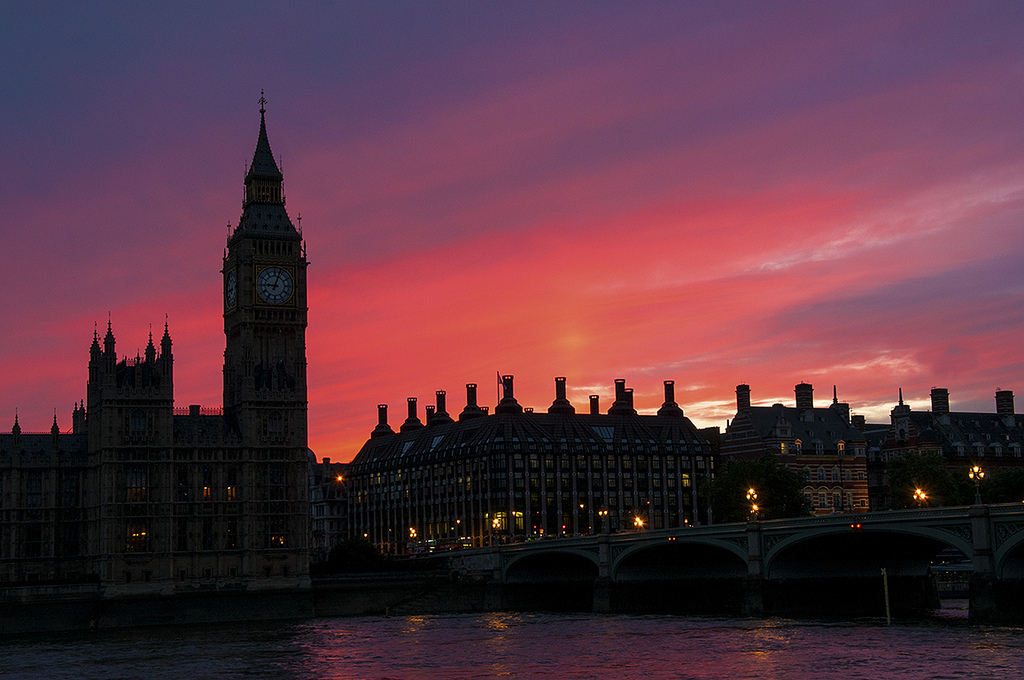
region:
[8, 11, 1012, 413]
The sky at dusk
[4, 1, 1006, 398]
A orange sky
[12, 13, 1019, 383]
A sky at dusk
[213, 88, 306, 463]
The clock tower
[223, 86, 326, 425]
A clock tower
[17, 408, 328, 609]
The building to the left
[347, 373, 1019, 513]
The building to the right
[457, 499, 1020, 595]
The concrete bridge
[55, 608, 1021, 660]
The body of water being shown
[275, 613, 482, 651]
Sunset reflected in the water.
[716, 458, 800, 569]
Lights on the side of the bridge.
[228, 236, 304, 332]
Clock on the side of the building.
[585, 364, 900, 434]
Thin rays of the sun behind the buildings.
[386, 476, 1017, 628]
Bridge between two of the buildings.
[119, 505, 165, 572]
Dim light between the windows.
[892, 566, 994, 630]
Small sign underneath the bridge.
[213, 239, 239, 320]
Side view from a clock on the side.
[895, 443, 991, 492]
Bunch of lights on the small building.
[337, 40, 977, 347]
Sky is purple and pink in color.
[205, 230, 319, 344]
Two face of clock in the tower.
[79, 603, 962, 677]
Reflection is seen in the river.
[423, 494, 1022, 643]
Bridge is above the river.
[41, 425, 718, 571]
Windows are attached to the building wall.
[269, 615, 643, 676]
Water is blue color.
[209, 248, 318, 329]
Time shown is 9.05.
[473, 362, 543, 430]
Flag pole is in top of the building.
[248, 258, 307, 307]
white clock with black hands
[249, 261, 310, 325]
white clock with roman numerals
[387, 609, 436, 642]
reflection of orange light on the water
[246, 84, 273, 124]
pointed design on top of clock tower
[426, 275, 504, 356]
orange area of clouds in the sky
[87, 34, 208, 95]
purplish blue area of clouds in the sky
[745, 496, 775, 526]
golden colored street light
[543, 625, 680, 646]
purple colored reflections in the water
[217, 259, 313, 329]
two clocks on the top of a clock tower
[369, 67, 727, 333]
Sky is pink and blue color.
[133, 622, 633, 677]
water is blue color.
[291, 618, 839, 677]
Reflection is seen in water.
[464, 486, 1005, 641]
Bridge is across the river.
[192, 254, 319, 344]
Two face of clock is seen in tower.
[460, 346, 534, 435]
Flag is in top of the building.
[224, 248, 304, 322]
9.05 is the time shown in clock.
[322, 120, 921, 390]
The sky is red.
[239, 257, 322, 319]
A clock on top of the tower.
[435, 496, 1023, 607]
A bridge by the building.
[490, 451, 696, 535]
The lights are on inside the building.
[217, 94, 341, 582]
The tower is tall.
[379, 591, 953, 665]
Water under the bridge.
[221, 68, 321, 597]
clock tower beside the river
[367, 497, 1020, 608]
bridge over the river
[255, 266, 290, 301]
clock on the tower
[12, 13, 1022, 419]
purple pink and blue sky above the buildings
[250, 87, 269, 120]
spire on the tower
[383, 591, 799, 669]
light reflections on the river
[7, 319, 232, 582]
building the tower is attached to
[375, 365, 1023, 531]
buildings with many chimneys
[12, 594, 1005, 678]
river under the bridge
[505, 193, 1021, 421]
clouds in the multicolored sky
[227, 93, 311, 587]
big ben tower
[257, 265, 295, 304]
a clock on a tower